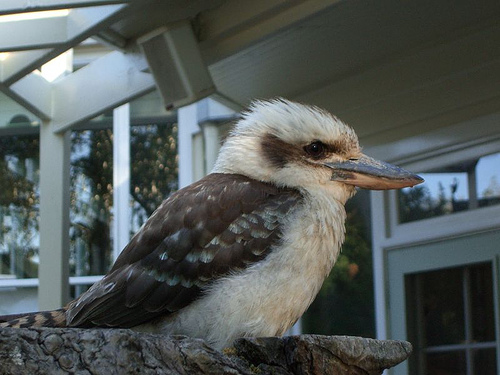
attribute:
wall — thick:
[160, 100, 400, 168]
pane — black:
[413, 271, 468, 348]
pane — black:
[466, 260, 497, 344]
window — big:
[395, 231, 497, 373]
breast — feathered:
[304, 194, 365, 286]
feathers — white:
[200, 251, 213, 263]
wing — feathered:
[49, 168, 375, 365]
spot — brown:
[259, 127, 307, 169]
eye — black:
[302, 134, 329, 164]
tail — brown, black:
[4, 286, 90, 330]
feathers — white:
[156, 245, 168, 263]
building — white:
[4, 8, 495, 373]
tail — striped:
[1, 309, 70, 331]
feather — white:
[115, 119, 462, 360]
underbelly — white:
[208, 201, 350, 341]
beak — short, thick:
[331, 150, 425, 190]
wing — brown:
[70, 172, 306, 332]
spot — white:
[249, 228, 271, 241]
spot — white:
[157, 247, 171, 267]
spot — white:
[198, 251, 213, 263]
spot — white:
[195, 219, 204, 231]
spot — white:
[227, 218, 244, 236]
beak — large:
[335, 146, 429, 198]